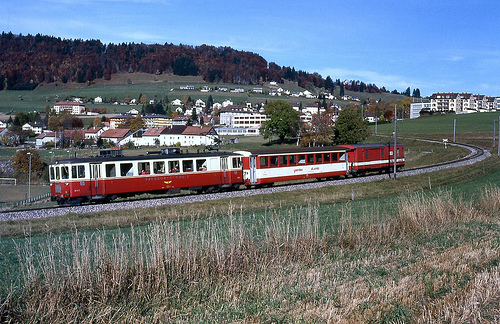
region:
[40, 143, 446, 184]
A train on train tracks.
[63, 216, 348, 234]
The grass is green.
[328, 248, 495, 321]
The grass is dry.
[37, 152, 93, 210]
Where the conductor sits.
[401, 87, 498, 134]
Large houses on a hill.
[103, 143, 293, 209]
The train is white and red.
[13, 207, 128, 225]
Gravel next to the tracks.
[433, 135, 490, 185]
The rails of the track is black.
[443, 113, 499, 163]
Poles next to the tracks.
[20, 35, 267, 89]
Trees in the background.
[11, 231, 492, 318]
Tall brown grass in the foreground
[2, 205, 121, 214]
Gravel next to the track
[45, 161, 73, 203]
Front of the train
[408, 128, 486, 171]
Empty track behind the train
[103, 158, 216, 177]
White windows in the train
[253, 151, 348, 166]
Red windows in the train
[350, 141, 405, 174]
Last car of the train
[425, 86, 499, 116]
Row of identical buildings on the far right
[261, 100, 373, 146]
Group of large trees just behind the train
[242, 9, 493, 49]
Bright blue sky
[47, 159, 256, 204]
red and white train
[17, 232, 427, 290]
dry brown tall grass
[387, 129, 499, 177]
long winding railroad track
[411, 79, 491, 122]
apartment building in background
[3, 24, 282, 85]
tall dark green trees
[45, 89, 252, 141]
small pricey housing area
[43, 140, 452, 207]
three car cargo train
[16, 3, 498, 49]
blue clear open sky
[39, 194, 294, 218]
gray colored gravel ad rocks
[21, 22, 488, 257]
train traveling thru city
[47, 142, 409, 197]
Red train on track.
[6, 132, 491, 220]
Rocks around train tracks.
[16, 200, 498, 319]
Tall grasses in the field.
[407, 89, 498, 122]
Apartment buildings in the background.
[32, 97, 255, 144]
Buildings with red roofs.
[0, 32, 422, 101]
Trees on the hills.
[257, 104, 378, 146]
Green trees in the village.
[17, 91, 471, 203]
Lights around the village.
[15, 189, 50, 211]
Fence close to the tracks.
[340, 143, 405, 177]
Red caboose with one white stripe.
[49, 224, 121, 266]
tall tan grass in field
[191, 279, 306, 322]
sparse green grass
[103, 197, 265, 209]
long gray gravel road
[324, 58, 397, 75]
white clouds in the sky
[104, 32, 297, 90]
large selection of green trees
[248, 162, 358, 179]
white section train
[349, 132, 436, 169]
caboose on train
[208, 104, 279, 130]
white building with glass windows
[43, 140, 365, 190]
large red and white train on track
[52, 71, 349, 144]
small village in the background